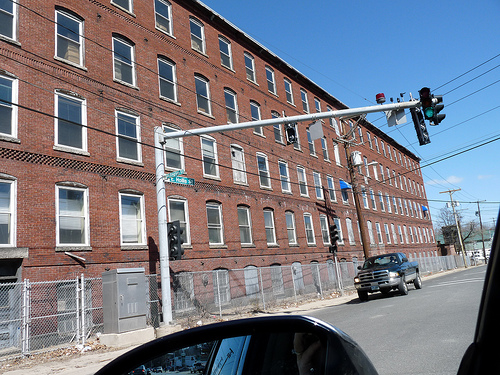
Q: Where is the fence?
A: Beside the building.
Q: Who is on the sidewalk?
A: No one.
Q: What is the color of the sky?
A: Blue and white.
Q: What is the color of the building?
A: Red.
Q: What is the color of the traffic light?
A: Green.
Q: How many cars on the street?
A: Two.